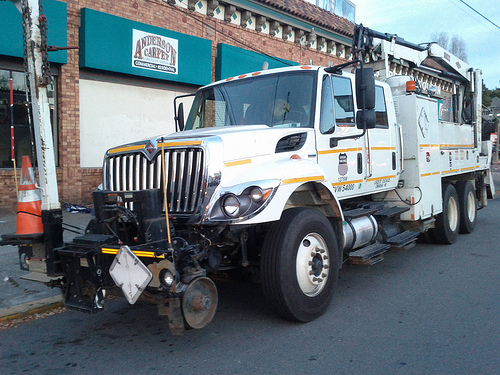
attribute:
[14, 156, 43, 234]
cone — orange, crushed, attached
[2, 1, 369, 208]
facade — brick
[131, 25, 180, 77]
sign — white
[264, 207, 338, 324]
tire — large, black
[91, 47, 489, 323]
truck — large, parked, white, big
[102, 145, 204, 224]
grill — metal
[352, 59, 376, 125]
mirror — large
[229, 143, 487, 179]
stripes — yellow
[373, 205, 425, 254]
steps — black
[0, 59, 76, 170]
window — big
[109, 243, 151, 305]
diamond — white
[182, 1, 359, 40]
cornice — ornate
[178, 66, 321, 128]
windshield — tinted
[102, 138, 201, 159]
stripe — yellow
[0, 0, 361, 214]
bricks — brown